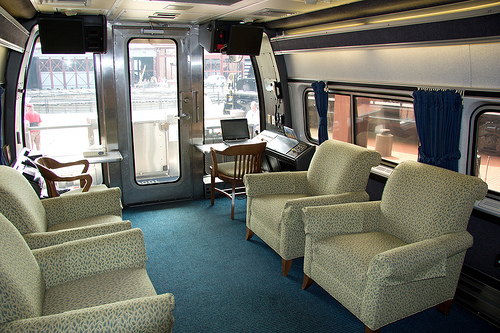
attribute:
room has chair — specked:
[1, 139, 479, 332]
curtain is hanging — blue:
[412, 86, 463, 174]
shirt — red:
[22, 104, 38, 129]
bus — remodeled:
[2, 5, 494, 330]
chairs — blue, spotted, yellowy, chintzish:
[1, 138, 490, 330]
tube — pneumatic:
[139, 25, 169, 35]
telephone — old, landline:
[272, 76, 284, 105]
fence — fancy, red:
[33, 51, 96, 89]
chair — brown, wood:
[26, 153, 93, 198]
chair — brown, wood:
[202, 136, 265, 221]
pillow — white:
[217, 154, 258, 177]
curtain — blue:
[413, 85, 460, 175]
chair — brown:
[206, 138, 266, 228]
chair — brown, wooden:
[32, 153, 95, 198]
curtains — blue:
[306, 76, 464, 172]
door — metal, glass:
[106, 24, 196, 214]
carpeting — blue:
[130, 189, 497, 330]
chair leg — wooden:
[275, 247, 293, 277]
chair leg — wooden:
[241, 225, 259, 243]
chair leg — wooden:
[297, 276, 313, 294]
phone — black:
[270, 78, 288, 101]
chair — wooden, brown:
[201, 138, 275, 221]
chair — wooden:
[22, 147, 92, 197]